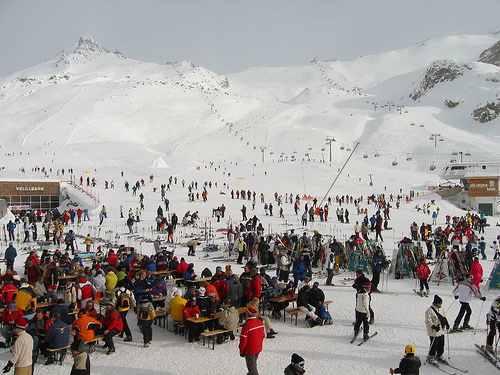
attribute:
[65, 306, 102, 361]
person — orange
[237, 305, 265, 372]
person — red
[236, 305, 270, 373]
man — red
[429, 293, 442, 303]
hat — black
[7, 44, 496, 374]
snow — part of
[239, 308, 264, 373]
man — red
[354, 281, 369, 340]
jacket — white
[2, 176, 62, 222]
brick building — bricked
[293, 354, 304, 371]
head — head of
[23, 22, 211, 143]
mountain — large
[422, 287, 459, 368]
man — ski stick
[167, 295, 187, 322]
jacket — yellow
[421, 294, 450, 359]
man — white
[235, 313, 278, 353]
jacket — red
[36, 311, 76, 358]
jacket — blue